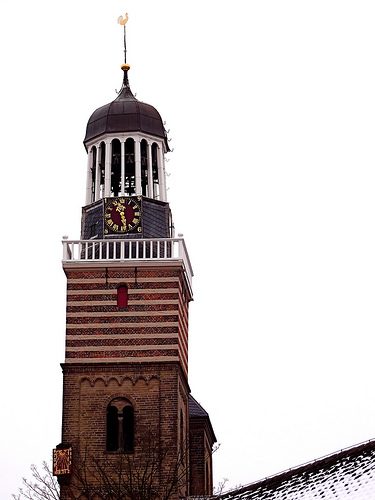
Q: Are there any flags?
A: No, there are no flags.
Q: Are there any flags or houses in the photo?
A: No, there are no flags or houses.